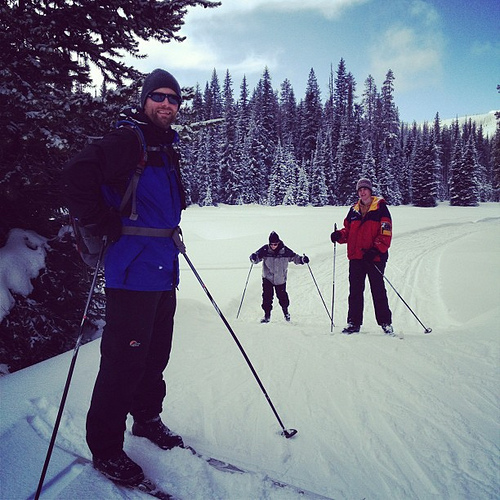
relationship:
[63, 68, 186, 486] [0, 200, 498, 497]
people on snow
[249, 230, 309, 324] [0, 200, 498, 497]
people on snow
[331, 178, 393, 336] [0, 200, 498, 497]
people on snow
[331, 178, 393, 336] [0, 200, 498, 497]
people are in snow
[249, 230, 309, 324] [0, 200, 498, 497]
people are in snow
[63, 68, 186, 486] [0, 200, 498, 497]
people are in snow